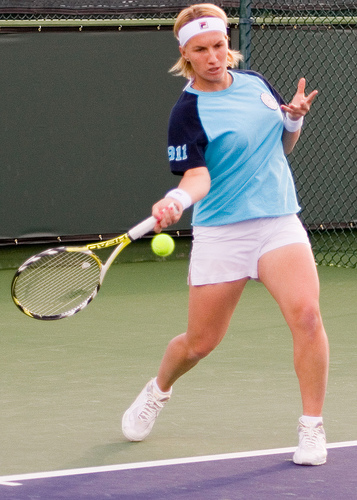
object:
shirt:
[166, 67, 300, 229]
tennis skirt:
[186, 211, 310, 285]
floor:
[1, 270, 356, 499]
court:
[0, 20, 355, 496]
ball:
[150, 232, 174, 256]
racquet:
[10, 202, 178, 319]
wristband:
[165, 187, 192, 208]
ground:
[0, 235, 356, 498]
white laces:
[295, 422, 317, 450]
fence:
[241, 0, 355, 268]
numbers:
[179, 145, 187, 160]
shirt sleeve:
[166, 98, 209, 176]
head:
[172, 3, 235, 82]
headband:
[175, 17, 226, 47]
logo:
[198, 17, 208, 34]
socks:
[153, 375, 173, 397]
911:
[167, 144, 188, 164]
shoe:
[290, 414, 328, 469]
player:
[119, 0, 331, 465]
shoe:
[121, 376, 172, 444]